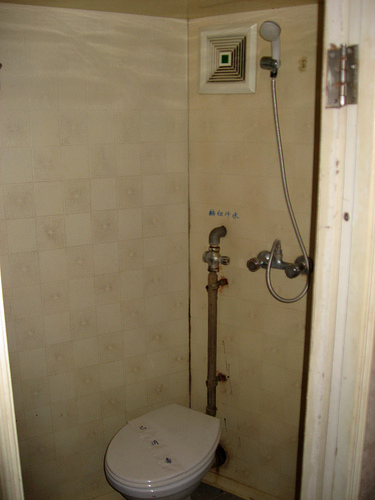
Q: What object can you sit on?
A: A toilet.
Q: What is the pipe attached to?
A: Wall.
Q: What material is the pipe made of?
A: Metal.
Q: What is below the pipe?
A: Toilet.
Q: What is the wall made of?
A: Tile.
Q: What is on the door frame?
A: Hinge.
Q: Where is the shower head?
A: On the wall.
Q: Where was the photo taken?
A: In a bathroom.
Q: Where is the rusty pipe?
A: On the wall.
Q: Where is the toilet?
A: Against the wall.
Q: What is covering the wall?
A: Wallpaper.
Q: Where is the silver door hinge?
A: On the door frame.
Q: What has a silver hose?
A: The shower head.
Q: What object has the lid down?
A: The toilet.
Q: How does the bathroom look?
A: Dirty.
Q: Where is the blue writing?
A: On the wall above the pipe.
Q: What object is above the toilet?
A: Pipe.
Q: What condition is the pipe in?
A: Rusty.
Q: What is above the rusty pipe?
A: Vent.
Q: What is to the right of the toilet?
A: Shower.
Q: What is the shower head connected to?
A: Hose.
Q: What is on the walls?
A: Tiles.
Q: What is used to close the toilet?
A: Lid.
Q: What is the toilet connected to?
A: Wall.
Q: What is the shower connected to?
A: Wall.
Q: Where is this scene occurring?
A: A bathroom.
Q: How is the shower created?
A: With shower spayer above toilet.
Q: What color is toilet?
A: White.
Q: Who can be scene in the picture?
A: No one.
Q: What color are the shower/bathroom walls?
A: Beige.